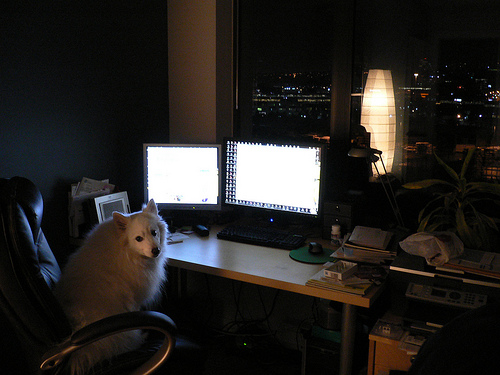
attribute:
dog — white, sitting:
[69, 200, 172, 371]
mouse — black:
[307, 241, 325, 257]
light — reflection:
[358, 67, 394, 184]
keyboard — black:
[216, 224, 306, 250]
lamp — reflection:
[362, 66, 401, 181]